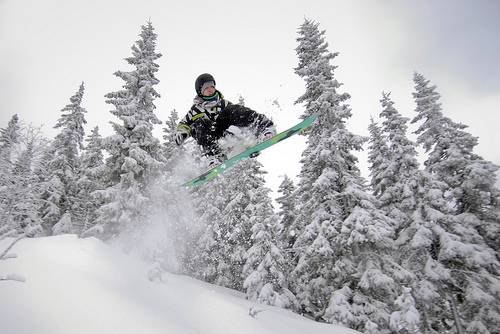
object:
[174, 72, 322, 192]
snowboarder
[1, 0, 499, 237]
air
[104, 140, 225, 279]
snow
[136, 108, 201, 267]
trees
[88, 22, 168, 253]
tree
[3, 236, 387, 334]
snow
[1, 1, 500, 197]
sky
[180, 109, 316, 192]
snowboard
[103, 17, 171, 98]
top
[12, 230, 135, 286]
top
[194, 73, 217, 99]
head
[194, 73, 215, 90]
bonnet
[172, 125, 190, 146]
right hand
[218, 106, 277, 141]
left leg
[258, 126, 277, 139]
left boot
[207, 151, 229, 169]
right boot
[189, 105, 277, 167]
pants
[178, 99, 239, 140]
jacket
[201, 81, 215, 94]
hat